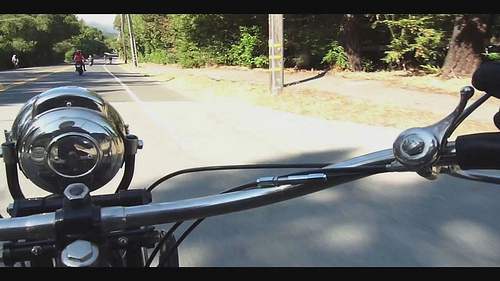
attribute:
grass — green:
[289, 92, 412, 128]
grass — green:
[172, 72, 256, 100]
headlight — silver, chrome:
[9, 92, 122, 199]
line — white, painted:
[101, 56, 198, 206]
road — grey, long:
[5, 57, 495, 277]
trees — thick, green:
[3, 15, 103, 67]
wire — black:
[159, 163, 260, 176]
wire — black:
[221, 177, 261, 192]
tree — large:
[324, 8, 498, 83]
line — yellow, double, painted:
[2, 63, 69, 93]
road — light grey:
[141, 79, 380, 158]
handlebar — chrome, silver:
[3, 84, 498, 236]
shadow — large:
[221, 188, 463, 248]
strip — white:
[100, 64, 141, 104]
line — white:
[109, 61, 141, 113]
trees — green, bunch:
[114, 12, 496, 70]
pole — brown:
[269, 12, 276, 92]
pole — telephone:
[264, 13, 289, 95]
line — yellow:
[5, 65, 62, 90]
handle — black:
[353, 67, 498, 199]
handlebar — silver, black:
[51, 83, 488, 266]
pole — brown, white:
[267, 13, 279, 98]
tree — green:
[4, 19, 39, 55]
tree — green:
[130, 8, 185, 61]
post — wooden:
[267, 12, 287, 101]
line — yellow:
[264, 58, 281, 75]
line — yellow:
[268, 38, 286, 55]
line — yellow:
[101, 66, 141, 102]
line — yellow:
[0, 66, 77, 100]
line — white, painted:
[103, 59, 143, 103]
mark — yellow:
[266, 39, 283, 49]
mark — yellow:
[268, 53, 283, 62]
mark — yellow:
[270, 65, 281, 74]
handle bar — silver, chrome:
[2, 95, 497, 252]